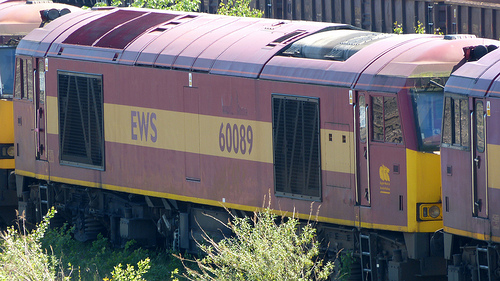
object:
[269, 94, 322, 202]
door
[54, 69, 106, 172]
door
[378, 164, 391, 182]
logo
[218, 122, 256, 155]
60089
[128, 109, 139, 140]
letter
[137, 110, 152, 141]
letter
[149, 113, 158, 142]
letter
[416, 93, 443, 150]
windscreen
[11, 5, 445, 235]
train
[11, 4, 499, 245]
car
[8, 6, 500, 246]
train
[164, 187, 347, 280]
bush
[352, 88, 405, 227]
door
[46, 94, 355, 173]
area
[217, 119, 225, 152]
number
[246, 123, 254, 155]
number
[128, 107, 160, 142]
ews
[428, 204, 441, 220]
light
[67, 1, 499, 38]
train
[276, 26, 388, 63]
opening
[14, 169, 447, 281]
bottom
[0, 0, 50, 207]
engine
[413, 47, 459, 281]
segment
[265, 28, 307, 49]
vent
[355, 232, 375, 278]
steps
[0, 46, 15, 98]
windshield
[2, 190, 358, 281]
grass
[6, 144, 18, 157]
light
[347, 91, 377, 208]
handrail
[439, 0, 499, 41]
car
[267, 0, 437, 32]
car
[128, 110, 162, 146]
writing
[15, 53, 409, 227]
side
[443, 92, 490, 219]
door